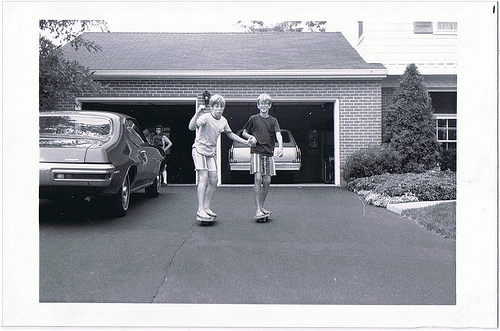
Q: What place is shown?
A: It is a garage.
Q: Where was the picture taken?
A: It was taken at the garage.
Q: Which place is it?
A: It is a garage.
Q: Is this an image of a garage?
A: Yes, it is showing a garage.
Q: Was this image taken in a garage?
A: Yes, it was taken in a garage.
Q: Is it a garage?
A: Yes, it is a garage.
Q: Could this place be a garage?
A: Yes, it is a garage.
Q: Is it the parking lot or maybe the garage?
A: It is the garage.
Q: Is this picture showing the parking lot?
A: No, the picture is showing the garage.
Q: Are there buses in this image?
A: No, there are no buses.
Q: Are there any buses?
A: No, there are no buses.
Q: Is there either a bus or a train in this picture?
A: No, there are no buses or trains.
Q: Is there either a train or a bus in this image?
A: No, there are no buses or trains.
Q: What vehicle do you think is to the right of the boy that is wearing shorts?
A: The vehicle is a car.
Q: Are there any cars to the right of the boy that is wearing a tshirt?
A: Yes, there is a car to the right of the boy.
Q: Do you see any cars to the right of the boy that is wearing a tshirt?
A: Yes, there is a car to the right of the boy.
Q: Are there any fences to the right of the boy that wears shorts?
A: No, there is a car to the right of the boy.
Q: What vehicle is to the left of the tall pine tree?
A: The vehicle is a car.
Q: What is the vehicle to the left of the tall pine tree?
A: The vehicle is a car.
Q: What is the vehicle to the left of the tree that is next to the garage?
A: The vehicle is a car.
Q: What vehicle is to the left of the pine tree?
A: The vehicle is a car.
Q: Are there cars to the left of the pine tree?
A: Yes, there is a car to the left of the pine tree.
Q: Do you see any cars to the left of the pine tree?
A: Yes, there is a car to the left of the pine tree.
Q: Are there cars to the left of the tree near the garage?
A: Yes, there is a car to the left of the pine tree.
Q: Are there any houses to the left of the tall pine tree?
A: No, there is a car to the left of the pine tree.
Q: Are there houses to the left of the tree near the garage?
A: No, there is a car to the left of the pine tree.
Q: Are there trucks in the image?
A: No, there are no trucks.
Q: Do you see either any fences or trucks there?
A: No, there are no trucks or fences.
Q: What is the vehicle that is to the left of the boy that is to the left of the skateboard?
A: The vehicle is a car.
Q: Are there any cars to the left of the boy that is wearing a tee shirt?
A: Yes, there is a car to the left of the boy.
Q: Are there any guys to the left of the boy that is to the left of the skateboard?
A: No, there is a car to the left of the boy.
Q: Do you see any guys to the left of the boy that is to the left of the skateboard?
A: No, there is a car to the left of the boy.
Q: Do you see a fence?
A: No, there are no fences.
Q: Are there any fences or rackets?
A: No, there are no fences or rackets.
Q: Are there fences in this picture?
A: No, there are no fences.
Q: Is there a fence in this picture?
A: No, there are no fences.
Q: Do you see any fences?
A: No, there are no fences.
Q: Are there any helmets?
A: No, there are no helmets.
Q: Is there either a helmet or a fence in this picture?
A: No, there are no helmets or fences.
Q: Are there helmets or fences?
A: No, there are no helmets or fences.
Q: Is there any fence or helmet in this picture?
A: No, there are no helmets or fences.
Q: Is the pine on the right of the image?
A: Yes, the pine is on the right of the image.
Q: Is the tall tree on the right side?
A: Yes, the pine is on the right of the image.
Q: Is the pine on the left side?
A: No, the pine is on the right of the image.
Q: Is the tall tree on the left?
A: No, the pine is on the right of the image.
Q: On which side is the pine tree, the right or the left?
A: The pine tree is on the right of the image.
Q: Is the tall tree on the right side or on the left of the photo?
A: The pine tree is on the right of the image.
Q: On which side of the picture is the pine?
A: The pine is on the right of the image.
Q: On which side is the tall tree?
A: The pine is on the right of the image.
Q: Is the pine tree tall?
A: Yes, the pine tree is tall.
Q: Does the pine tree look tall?
A: Yes, the pine tree is tall.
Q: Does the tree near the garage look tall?
A: Yes, the pine tree is tall.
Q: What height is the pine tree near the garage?
A: The pine is tall.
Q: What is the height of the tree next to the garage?
A: The pine is tall.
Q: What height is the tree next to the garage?
A: The pine is tall.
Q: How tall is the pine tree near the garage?
A: The pine is tall.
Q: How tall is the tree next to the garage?
A: The pine is tall.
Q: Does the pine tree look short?
A: No, the pine tree is tall.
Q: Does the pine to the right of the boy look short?
A: No, the pine is tall.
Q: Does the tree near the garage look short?
A: No, the pine is tall.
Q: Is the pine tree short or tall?
A: The pine tree is tall.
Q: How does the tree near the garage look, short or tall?
A: The pine tree is tall.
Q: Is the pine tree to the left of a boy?
A: No, the pine tree is to the right of a boy.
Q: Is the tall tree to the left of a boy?
A: No, the pine tree is to the right of a boy.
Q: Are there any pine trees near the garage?
A: Yes, there is a pine tree near the garage.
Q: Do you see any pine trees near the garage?
A: Yes, there is a pine tree near the garage.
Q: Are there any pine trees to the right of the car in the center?
A: Yes, there is a pine tree to the right of the car.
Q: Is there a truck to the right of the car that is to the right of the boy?
A: No, there is a pine tree to the right of the car.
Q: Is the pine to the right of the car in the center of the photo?
A: Yes, the pine is to the right of the car.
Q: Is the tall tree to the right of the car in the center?
A: Yes, the pine is to the right of the car.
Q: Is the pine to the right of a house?
A: No, the pine is to the right of the car.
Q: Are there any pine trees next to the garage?
A: Yes, there is a pine tree next to the garage.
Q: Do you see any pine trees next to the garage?
A: Yes, there is a pine tree next to the garage.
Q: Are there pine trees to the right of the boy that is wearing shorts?
A: Yes, there is a pine tree to the right of the boy.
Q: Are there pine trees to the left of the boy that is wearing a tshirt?
A: No, the pine tree is to the right of the boy.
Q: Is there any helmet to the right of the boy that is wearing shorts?
A: No, there is a pine tree to the right of the boy.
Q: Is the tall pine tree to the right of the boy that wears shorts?
A: Yes, the pine is to the right of the boy.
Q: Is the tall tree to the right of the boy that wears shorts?
A: Yes, the pine is to the right of the boy.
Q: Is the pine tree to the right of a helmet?
A: No, the pine tree is to the right of the boy.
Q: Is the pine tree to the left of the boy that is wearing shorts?
A: No, the pine tree is to the right of the boy.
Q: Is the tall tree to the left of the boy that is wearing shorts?
A: No, the pine tree is to the right of the boy.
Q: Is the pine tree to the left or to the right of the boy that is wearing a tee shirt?
A: The pine tree is to the right of the boy.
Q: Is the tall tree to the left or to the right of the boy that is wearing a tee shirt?
A: The pine tree is to the right of the boy.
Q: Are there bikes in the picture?
A: No, there are no bikes.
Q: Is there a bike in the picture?
A: No, there are no bikes.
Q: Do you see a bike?
A: No, there are no bikes.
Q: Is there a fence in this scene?
A: No, there are no fences.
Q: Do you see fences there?
A: No, there are no fences.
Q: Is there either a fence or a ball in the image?
A: No, there are no fences or balls.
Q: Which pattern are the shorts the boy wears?
A: The shorts are striped.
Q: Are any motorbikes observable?
A: No, there are no motorbikes.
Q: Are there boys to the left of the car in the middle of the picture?
A: Yes, there is a boy to the left of the car.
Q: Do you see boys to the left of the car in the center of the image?
A: Yes, there is a boy to the left of the car.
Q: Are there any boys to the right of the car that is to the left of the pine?
A: No, the boy is to the left of the car.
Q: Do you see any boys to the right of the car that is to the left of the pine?
A: No, the boy is to the left of the car.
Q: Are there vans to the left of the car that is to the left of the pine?
A: No, there is a boy to the left of the car.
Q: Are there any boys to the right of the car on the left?
A: Yes, there is a boy to the right of the car.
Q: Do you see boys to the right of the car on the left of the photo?
A: Yes, there is a boy to the right of the car.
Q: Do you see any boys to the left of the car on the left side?
A: No, the boy is to the right of the car.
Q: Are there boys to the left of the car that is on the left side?
A: No, the boy is to the right of the car.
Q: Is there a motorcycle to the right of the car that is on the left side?
A: No, there is a boy to the right of the car.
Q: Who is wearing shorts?
A: The boy is wearing shorts.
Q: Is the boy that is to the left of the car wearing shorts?
A: Yes, the boy is wearing shorts.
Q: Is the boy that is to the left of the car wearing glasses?
A: No, the boy is wearing shorts.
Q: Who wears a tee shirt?
A: The boy wears a tee shirt.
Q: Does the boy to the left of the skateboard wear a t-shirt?
A: Yes, the boy wears a t-shirt.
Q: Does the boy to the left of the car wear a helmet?
A: No, the boy wears a t-shirt.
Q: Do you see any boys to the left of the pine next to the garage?
A: Yes, there is a boy to the left of the pine tree.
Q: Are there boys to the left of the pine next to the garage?
A: Yes, there is a boy to the left of the pine tree.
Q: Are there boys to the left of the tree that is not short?
A: Yes, there is a boy to the left of the pine tree.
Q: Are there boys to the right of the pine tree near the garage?
A: No, the boy is to the left of the pine tree.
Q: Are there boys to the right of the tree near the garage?
A: No, the boy is to the left of the pine tree.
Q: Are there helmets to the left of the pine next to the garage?
A: No, there is a boy to the left of the pine.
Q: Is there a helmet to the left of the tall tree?
A: No, there is a boy to the left of the pine.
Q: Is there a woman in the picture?
A: No, there are no women.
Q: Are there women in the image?
A: No, there are no women.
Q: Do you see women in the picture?
A: No, there are no women.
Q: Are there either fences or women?
A: No, there are no women or fences.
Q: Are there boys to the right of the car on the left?
A: Yes, there is a boy to the right of the car.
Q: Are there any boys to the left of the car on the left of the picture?
A: No, the boy is to the right of the car.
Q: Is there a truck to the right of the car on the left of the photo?
A: No, there is a boy to the right of the car.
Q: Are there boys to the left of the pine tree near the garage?
A: Yes, there is a boy to the left of the pine.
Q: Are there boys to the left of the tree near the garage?
A: Yes, there is a boy to the left of the pine.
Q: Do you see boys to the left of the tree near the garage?
A: Yes, there is a boy to the left of the pine.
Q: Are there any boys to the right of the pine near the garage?
A: No, the boy is to the left of the pine tree.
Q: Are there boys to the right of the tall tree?
A: No, the boy is to the left of the pine tree.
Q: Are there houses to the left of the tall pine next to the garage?
A: No, there is a boy to the left of the pine.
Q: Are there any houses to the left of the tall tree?
A: No, there is a boy to the left of the pine.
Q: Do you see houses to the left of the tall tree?
A: No, there is a boy to the left of the pine.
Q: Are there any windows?
A: Yes, there is a window.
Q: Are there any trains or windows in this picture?
A: Yes, there is a window.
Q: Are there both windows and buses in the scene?
A: No, there is a window but no buses.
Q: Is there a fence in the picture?
A: No, there are no fences.